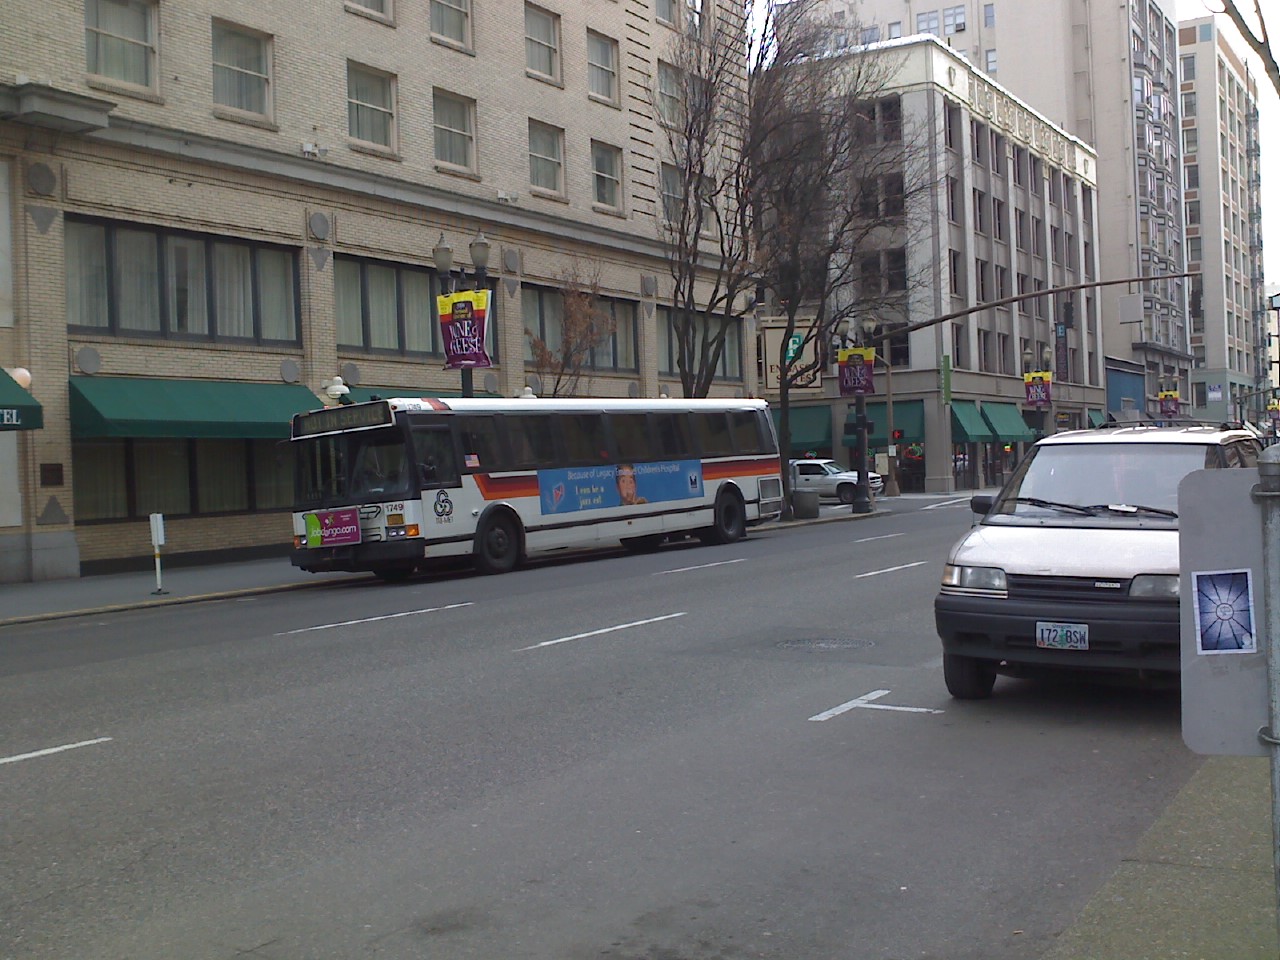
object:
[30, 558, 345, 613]
curb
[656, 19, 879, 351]
leaves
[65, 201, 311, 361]
windows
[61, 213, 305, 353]
curtains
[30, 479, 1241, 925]
street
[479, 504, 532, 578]
wheel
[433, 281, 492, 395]
streetlight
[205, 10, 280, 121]
window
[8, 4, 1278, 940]
city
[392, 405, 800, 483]
windows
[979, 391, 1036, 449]
awning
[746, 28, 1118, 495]
building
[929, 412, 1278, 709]
suv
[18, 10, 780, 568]
building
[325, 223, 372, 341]
window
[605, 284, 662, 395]
window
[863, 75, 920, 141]
window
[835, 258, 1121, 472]
light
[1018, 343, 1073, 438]
banner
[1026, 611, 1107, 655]
plate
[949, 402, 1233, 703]
car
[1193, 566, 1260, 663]
sticker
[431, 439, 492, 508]
flag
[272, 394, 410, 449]
display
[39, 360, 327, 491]
awning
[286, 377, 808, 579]
bus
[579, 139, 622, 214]
windows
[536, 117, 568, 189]
windows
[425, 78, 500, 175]
windows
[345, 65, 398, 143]
windows